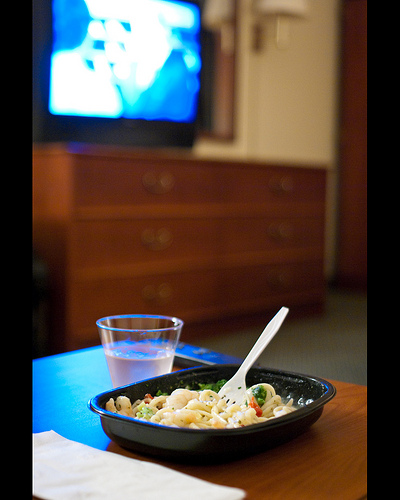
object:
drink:
[103, 343, 175, 385]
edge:
[96, 311, 185, 334]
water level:
[99, 352, 175, 388]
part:
[179, 350, 253, 372]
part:
[28, 327, 390, 498]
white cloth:
[36, 426, 231, 498]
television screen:
[47, 0, 204, 125]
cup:
[90, 305, 183, 384]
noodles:
[174, 394, 264, 428]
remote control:
[128, 330, 246, 371]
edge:
[253, 359, 338, 392]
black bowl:
[89, 363, 338, 471]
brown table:
[248, 377, 367, 499]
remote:
[149, 330, 261, 371]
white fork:
[216, 305, 311, 396]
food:
[106, 385, 302, 427]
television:
[49, 1, 196, 124]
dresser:
[57, 145, 336, 348]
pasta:
[184, 396, 263, 440]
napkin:
[31, 434, 235, 498]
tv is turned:
[46, 0, 204, 122]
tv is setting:
[49, 2, 203, 128]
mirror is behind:
[201, 1, 246, 154]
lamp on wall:
[255, 4, 306, 51]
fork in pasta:
[212, 305, 302, 395]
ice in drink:
[106, 341, 174, 357]